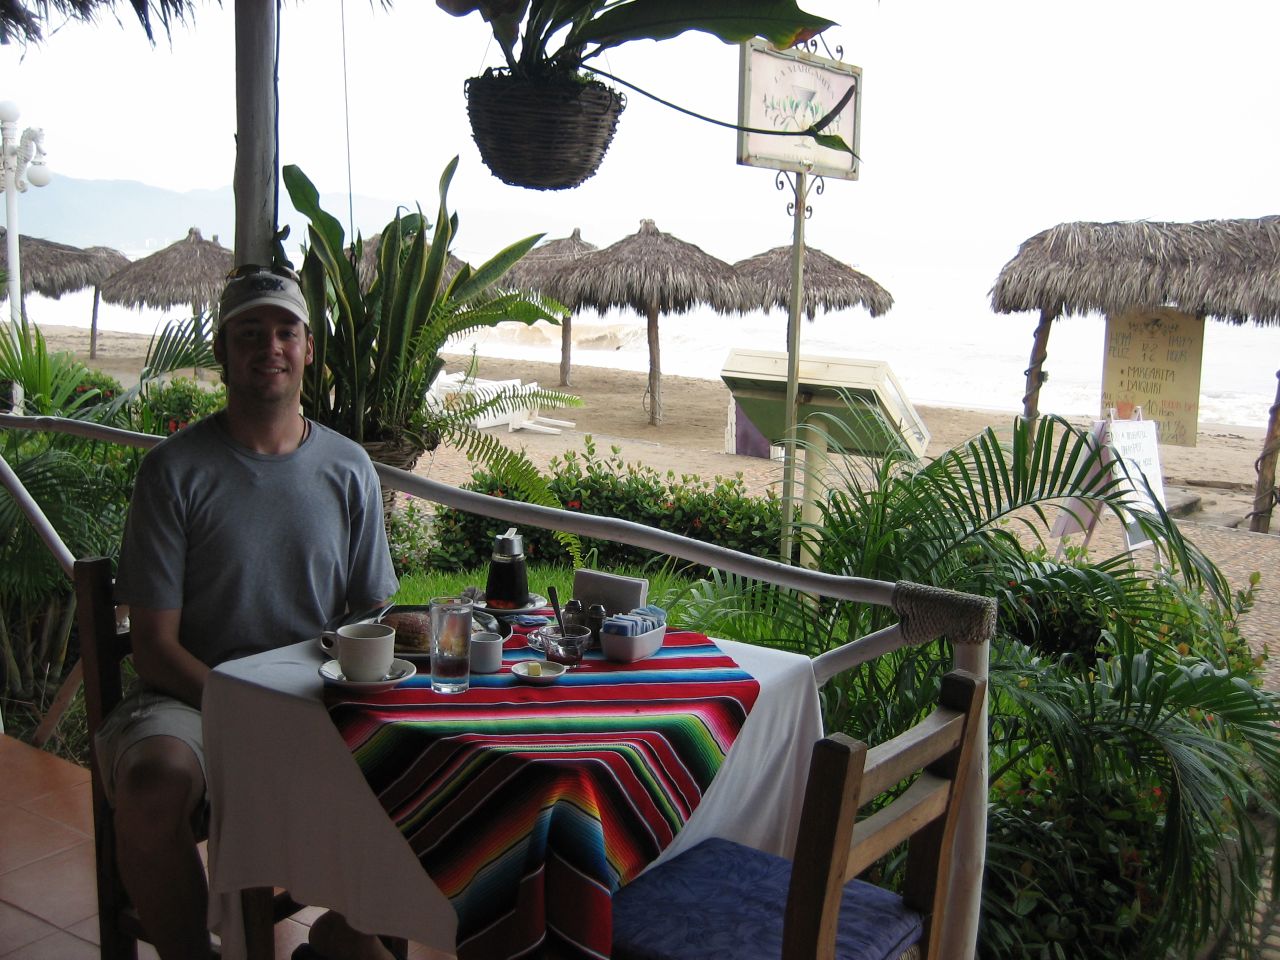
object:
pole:
[766, 169, 819, 573]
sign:
[738, 30, 864, 183]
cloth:
[326, 597, 760, 960]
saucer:
[318, 659, 418, 694]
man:
[81, 263, 415, 959]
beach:
[4, 310, 1278, 701]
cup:
[319, 622, 412, 682]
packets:
[604, 621, 631, 637]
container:
[597, 620, 669, 662]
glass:
[429, 594, 473, 696]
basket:
[459, 66, 624, 194]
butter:
[526, 659, 542, 677]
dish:
[506, 656, 570, 688]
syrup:
[483, 554, 530, 611]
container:
[480, 526, 533, 609]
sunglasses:
[225, 261, 303, 282]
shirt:
[119, 411, 406, 689]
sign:
[1101, 306, 1205, 448]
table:
[205, 600, 827, 957]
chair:
[614, 665, 984, 957]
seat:
[610, 834, 927, 957]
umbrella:
[711, 244, 894, 319]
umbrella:
[553, 217, 742, 421]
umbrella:
[486, 227, 602, 387]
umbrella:
[98, 230, 236, 379]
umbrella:
[81, 245, 132, 359]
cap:
[217, 272, 313, 331]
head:
[213, 272, 317, 401]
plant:
[439, 1, 860, 197]